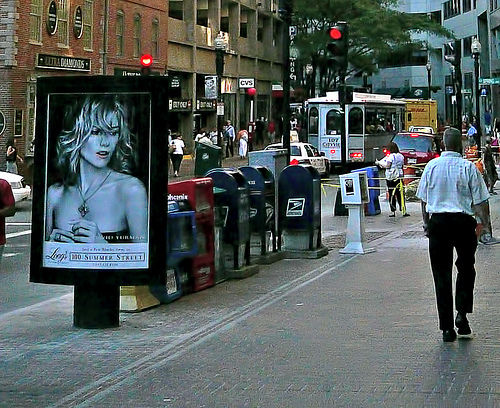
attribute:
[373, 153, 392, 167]
newspaper — near curb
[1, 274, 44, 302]
street — city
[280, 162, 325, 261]
mail box — USPS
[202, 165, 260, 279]
mailbox — blue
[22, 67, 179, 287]
woman — blond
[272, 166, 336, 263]
mailbox — blue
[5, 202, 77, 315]
street — busy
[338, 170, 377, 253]
newspaper stand — white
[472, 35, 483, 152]
lamp post — antique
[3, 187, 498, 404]
cobblestone street — gray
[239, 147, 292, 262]
post — blue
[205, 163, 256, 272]
mail post — blue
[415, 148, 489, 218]
shirt — white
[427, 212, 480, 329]
pants — black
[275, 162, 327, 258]
mailbox — blue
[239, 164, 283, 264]
mailbox — blue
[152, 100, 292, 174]
street — busy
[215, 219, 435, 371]
sidewalk — brick